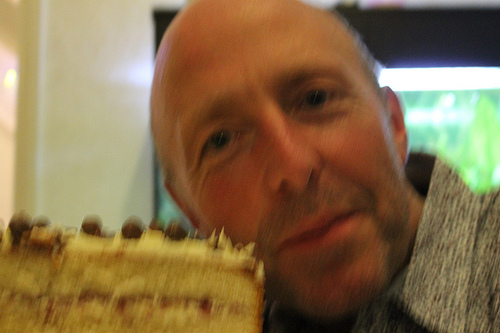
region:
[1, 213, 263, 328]
sliced layers of cake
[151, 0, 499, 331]
man is posing by cake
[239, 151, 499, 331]
grey and red shirt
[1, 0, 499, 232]
creme colored wall behind cake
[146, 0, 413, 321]
person is bald on top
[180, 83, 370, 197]
person has crows feet by eyes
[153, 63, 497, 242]
large lit aquarium behind person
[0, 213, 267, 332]
a slice of cake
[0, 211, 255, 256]
toppings on top of cake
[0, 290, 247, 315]
filling inside of cake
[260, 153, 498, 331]
gray shirt on man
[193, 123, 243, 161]
eye on man's face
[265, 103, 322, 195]
nose on man's face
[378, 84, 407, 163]
ear on man's head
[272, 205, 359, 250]
mouth on man's face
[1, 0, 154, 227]
white wall behind man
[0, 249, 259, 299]
top layer of cake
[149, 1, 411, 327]
man's face on tilted head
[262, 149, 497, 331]
open collar of shirt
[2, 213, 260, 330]
side of cut cake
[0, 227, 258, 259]
frosting on top of cake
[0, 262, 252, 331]
layers in cut cake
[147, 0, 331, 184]
bald head of man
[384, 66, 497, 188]
glowing light in fish tank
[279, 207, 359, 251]
lips of closed mouth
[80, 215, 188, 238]
chocolate balls on frosting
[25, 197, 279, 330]
a slice of cake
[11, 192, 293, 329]
a slice of cake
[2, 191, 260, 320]
a slice of cake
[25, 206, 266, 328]
a slice of cake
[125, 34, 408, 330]
man's face beside the cake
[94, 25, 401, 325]
man's face beside the cake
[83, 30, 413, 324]
man's face beside the cake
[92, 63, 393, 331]
man's face beside the cake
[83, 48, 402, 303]
man's face beside the cake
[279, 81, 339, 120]
man's sparkling black eye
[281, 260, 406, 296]
hair on man's face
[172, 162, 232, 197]
wrinkle on side of man's face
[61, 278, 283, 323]
chocolate frosting in middle of cake slice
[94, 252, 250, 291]
piece of yellow cake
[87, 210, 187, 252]
chocolate balls on top of cake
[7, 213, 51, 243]
black walnut on top of cake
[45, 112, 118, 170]
white paint on the wall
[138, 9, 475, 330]
this is a man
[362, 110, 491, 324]
this is a shirt collar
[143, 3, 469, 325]
man has head tilted